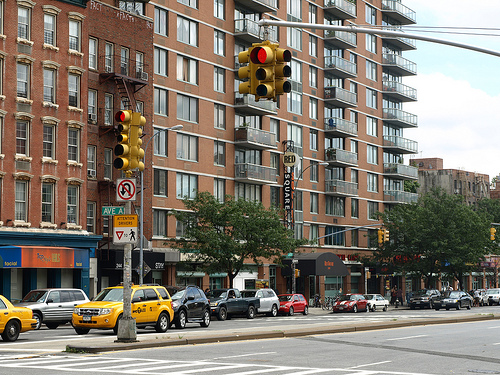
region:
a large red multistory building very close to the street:
[0, 0, 413, 333]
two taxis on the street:
[0, 278, 175, 351]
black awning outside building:
[273, 203, 348, 286]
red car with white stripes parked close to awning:
[294, 252, 366, 317]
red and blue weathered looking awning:
[0, 241, 97, 277]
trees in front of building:
[163, 155, 495, 312]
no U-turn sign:
[112, 175, 144, 207]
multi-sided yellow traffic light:
[229, 13, 300, 99]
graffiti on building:
[81, 0, 162, 30]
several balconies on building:
[323, 1, 419, 208]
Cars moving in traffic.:
[73, 280, 215, 336]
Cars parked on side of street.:
[260, 286, 390, 313]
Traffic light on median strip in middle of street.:
[98, 103, 167, 348]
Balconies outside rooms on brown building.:
[319, 31, 427, 211]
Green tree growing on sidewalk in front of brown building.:
[166, 192, 309, 313]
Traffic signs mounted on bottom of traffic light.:
[108, 178, 148, 250]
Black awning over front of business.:
[285, 247, 350, 279]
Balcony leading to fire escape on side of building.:
[99, 46, 155, 153]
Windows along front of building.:
[11, 6, 87, 235]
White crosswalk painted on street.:
[14, 345, 393, 373]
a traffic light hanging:
[229, 37, 304, 109]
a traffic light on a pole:
[97, 94, 159, 175]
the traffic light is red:
[100, 100, 165, 180]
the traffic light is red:
[223, 37, 303, 107]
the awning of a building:
[281, 245, 368, 294]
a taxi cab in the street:
[61, 285, 173, 330]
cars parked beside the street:
[202, 275, 486, 305]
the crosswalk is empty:
[23, 345, 401, 374]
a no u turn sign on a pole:
[105, 169, 148, 204]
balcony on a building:
[315, 47, 370, 194]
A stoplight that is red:
[230, 33, 295, 106]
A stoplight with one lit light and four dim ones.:
[108, 104, 148, 177]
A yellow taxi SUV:
[68, 280, 178, 335]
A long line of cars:
[17, 287, 498, 327]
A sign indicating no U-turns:
[109, 175, 143, 205]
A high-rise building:
[1, 0, 421, 277]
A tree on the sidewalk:
[371, 187, 498, 307]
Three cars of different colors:
[206, 283, 311, 319]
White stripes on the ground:
[0, 338, 386, 373]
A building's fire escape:
[89, 38, 159, 143]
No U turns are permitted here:
[107, 172, 151, 212]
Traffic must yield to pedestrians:
[103, 206, 147, 253]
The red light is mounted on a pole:
[108, 103, 147, 348]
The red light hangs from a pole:
[238, 11, 498, 99]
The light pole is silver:
[232, 6, 497, 80]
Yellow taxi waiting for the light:
[70, 271, 174, 345]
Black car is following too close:
[156, 280, 220, 330]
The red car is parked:
[278, 290, 311, 317]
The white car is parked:
[363, 287, 396, 314]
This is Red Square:
[277, 131, 303, 253]